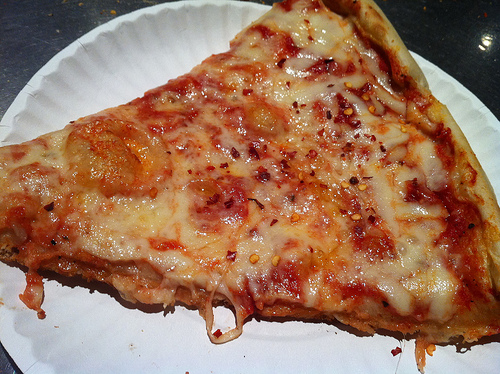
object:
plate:
[2, 1, 500, 373]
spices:
[344, 108, 354, 115]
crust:
[359, 1, 499, 293]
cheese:
[0, 1, 499, 374]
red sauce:
[238, 21, 493, 316]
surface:
[0, 2, 500, 374]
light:
[478, 35, 493, 50]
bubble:
[65, 115, 173, 196]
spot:
[315, 23, 341, 46]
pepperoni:
[185, 175, 249, 229]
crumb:
[391, 347, 402, 356]